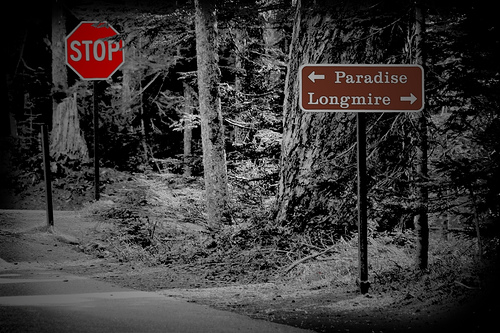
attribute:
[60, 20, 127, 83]
stop sign — red, white, octagon, lettered, octagonal, in ground, snowy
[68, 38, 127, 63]
letters — printed, white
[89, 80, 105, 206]
pole — black, metal, connected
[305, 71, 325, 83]
arrow — pointing right, pointing, heading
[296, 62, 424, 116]
sign — brown, white, directing, directional, rectangular, written, lettered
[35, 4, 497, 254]
trees — trunked, oak, big, shadowy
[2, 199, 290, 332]
street — black, white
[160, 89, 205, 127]
branch — attached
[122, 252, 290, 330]
dirt — present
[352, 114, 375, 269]
post — straight